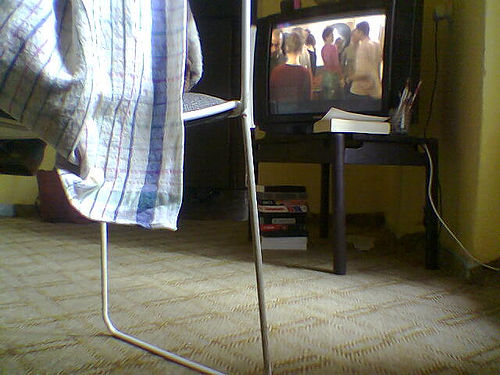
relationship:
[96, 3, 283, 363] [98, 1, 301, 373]
frame on chair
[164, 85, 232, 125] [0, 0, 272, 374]
seat on chair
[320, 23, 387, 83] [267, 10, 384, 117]
people on tv screen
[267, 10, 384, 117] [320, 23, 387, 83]
tv screen with people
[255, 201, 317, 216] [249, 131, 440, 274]
movie under stand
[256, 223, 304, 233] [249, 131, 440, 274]
movie under stand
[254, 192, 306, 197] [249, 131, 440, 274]
movie under stand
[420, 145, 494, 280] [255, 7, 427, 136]
white wire with television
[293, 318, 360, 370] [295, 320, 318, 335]
rug with line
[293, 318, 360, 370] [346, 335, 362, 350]
rug with line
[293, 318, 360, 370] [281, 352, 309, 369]
rug with line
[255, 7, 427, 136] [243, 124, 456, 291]
television on stand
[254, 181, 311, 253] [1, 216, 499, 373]
books on floor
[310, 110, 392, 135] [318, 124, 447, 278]
book on chair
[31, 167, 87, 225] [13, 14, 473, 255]
purse in background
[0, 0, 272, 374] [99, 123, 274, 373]
chair has silver bottom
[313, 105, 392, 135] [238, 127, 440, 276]
book on table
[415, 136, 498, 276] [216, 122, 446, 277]
cord on table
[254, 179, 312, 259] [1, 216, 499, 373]
books on floor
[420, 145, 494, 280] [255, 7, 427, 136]
white wire connected from television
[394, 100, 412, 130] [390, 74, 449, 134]
cup with utensils